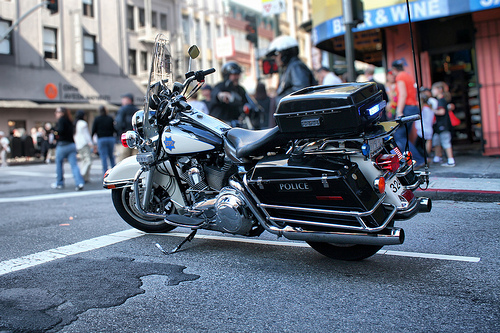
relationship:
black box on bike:
[275, 76, 386, 144] [66, 48, 451, 279]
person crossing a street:
[86, 100, 118, 180] [9, 161, 101, 266]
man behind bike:
[265, 33, 320, 109] [98, 32, 437, 262]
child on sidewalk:
[417, 76, 458, 162] [402, 150, 498, 179]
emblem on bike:
[163, 133, 177, 151] [101, 32, 433, 261]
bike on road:
[101, 32, 433, 261] [3, 171, 499, 329]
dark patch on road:
[0, 250, 202, 330] [1, 251, 170, 330]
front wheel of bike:
[83, 186, 202, 229] [98, 32, 437, 262]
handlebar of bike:
[178, 65, 215, 101] [98, 32, 437, 262]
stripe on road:
[10, 206, 101, 283] [3, 171, 499, 329]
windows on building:
[0, 0, 171, 73] [1, 0, 176, 147]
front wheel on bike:
[111, 183, 194, 234] [101, 32, 433, 261]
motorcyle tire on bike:
[299, 206, 395, 261] [101, 32, 433, 261]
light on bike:
[368, 151, 400, 175] [101, 32, 433, 261]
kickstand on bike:
[150, 226, 202, 257] [101, 32, 433, 261]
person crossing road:
[49, 109, 81, 191] [0, 171, 500, 333]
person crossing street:
[50, 106, 86, 191] [1, 147, 141, 247]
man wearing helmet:
[265, 33, 314, 110] [265, 35, 300, 63]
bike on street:
[101, 32, 433, 261] [45, 197, 435, 329]